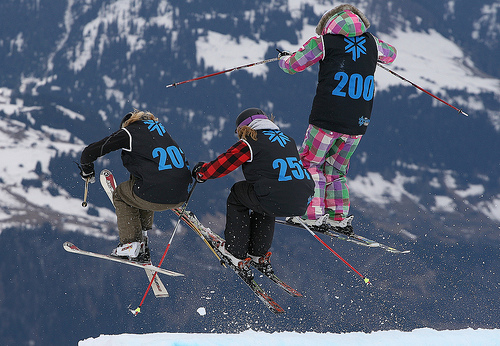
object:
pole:
[167, 53, 287, 89]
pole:
[376, 62, 469, 119]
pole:
[135, 182, 201, 311]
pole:
[293, 218, 370, 285]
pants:
[300, 123, 362, 221]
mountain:
[1, 0, 495, 345]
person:
[277, 5, 398, 230]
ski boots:
[285, 213, 328, 234]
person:
[191, 108, 316, 270]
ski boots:
[213, 239, 252, 267]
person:
[79, 107, 191, 260]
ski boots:
[112, 241, 145, 262]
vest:
[309, 33, 379, 135]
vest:
[240, 128, 317, 217]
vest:
[123, 111, 192, 205]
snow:
[78, 324, 496, 345]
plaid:
[197, 140, 249, 183]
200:
[330, 72, 375, 102]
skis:
[274, 211, 413, 255]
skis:
[171, 206, 304, 316]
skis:
[62, 169, 184, 298]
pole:
[81, 177, 89, 208]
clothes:
[278, 3, 396, 219]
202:
[151, 147, 193, 170]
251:
[271, 156, 311, 182]